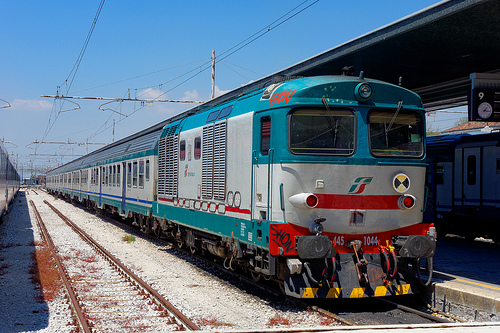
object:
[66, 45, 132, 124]
lines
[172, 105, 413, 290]
trains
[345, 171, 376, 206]
logo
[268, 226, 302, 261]
graffiti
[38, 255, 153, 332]
tracks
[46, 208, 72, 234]
gravel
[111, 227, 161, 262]
grass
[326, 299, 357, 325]
track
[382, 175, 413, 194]
valves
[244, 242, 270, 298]
wheels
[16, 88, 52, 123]
cloud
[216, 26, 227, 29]
sky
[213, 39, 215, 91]
pole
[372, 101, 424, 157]
front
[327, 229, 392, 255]
numbers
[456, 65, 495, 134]
clock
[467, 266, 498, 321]
platform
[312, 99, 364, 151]
windshield wiper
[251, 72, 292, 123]
roof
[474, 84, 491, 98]
number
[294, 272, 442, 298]
buffers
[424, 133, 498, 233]
train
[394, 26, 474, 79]
station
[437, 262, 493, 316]
line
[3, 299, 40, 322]
ground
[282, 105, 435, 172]
windows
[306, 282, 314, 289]
stripes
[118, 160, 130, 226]
door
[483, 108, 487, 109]
1:15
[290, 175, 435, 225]
headlights